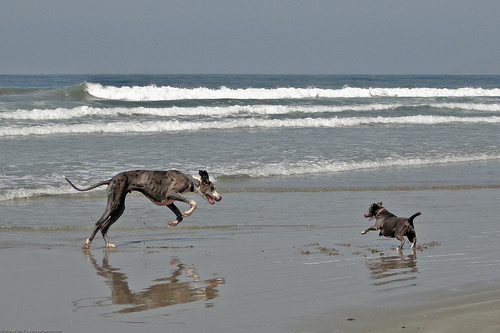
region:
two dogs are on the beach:
[46, 146, 438, 325]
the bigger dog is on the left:
[53, 142, 248, 261]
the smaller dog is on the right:
[346, 180, 433, 265]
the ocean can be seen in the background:
[20, 79, 485, 176]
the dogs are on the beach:
[57, 165, 495, 325]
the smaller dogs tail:
[405, 203, 432, 228]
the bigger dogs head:
[191, 164, 224, 211]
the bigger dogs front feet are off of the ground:
[164, 191, 203, 235]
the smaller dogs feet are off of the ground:
[356, 223, 387, 243]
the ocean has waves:
[95, 70, 462, 105]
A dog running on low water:
[128, 174, 180, 186]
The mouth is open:
[210, 198, 212, 201]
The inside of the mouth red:
[210, 199, 212, 201]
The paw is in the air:
[169, 220, 176, 225]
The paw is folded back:
[183, 211, 188, 216]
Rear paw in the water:
[108, 243, 113, 247]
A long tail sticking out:
[95, 183, 106, 185]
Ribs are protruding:
[152, 187, 159, 192]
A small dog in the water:
[385, 220, 398, 230]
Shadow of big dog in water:
[148, 289, 183, 298]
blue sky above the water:
[197, 12, 323, 75]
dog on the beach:
[55, 135, 235, 240]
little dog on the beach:
[337, 180, 437, 265]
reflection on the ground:
[140, 245, 225, 325]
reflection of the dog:
[140, 245, 225, 310]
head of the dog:
[190, 165, 240, 215]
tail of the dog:
[45, 166, 110, 216]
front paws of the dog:
[156, 195, 201, 240]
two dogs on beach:
[46, 75, 476, 285]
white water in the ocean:
[167, 68, 254, 116]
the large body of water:
[0, 72, 498, 199]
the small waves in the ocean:
[0, 79, 498, 139]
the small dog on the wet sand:
[360, 200, 420, 254]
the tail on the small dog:
[408, 211, 421, 221]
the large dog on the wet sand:
[63, 169, 223, 249]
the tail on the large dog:
[64, 174, 108, 194]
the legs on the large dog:
[82, 191, 196, 248]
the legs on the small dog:
[361, 223, 416, 251]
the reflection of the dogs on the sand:
[72, 248, 429, 319]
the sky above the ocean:
[0, 0, 499, 72]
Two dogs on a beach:
[63, 159, 432, 271]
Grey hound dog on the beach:
[54, 155, 228, 260]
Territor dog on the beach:
[355, 192, 424, 259]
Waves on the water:
[70, 76, 499, 104]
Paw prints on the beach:
[298, 244, 386, 268]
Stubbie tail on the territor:
[406, 209, 431, 231]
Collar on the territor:
[375, 208, 388, 216]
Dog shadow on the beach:
[72, 256, 226, 314]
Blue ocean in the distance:
[2, 66, 497, 89]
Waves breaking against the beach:
[5, 85, 498, 176]